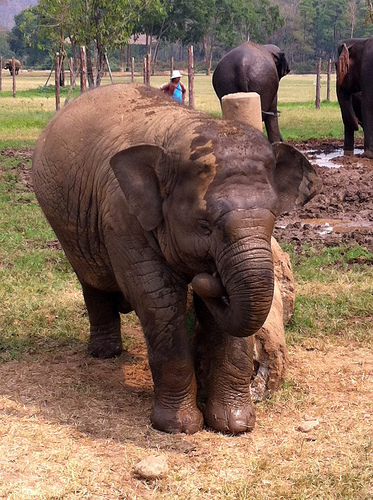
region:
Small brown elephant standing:
[9, 68, 307, 428]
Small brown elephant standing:
[198, 35, 370, 220]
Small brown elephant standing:
[318, 31, 371, 162]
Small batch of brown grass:
[21, 415, 61, 469]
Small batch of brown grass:
[347, 458, 366, 491]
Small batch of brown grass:
[300, 455, 317, 498]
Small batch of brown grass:
[239, 465, 269, 499]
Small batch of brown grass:
[199, 467, 230, 498]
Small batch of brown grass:
[109, 453, 127, 496]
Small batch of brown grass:
[74, 377, 142, 440]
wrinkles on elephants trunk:
[234, 247, 262, 314]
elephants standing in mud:
[223, 25, 372, 139]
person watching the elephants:
[156, 67, 193, 107]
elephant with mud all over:
[143, 123, 284, 435]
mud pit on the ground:
[282, 129, 362, 251]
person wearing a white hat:
[159, 64, 196, 105]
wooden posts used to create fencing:
[49, 47, 70, 109]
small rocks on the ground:
[120, 415, 333, 488]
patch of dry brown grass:
[18, 333, 360, 493]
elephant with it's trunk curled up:
[142, 133, 282, 414]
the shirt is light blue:
[176, 91, 180, 97]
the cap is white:
[170, 71, 184, 76]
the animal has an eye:
[199, 223, 212, 230]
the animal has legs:
[127, 334, 253, 432]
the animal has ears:
[107, 144, 156, 229]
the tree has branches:
[111, 1, 147, 35]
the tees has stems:
[137, 37, 155, 50]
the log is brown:
[187, 48, 193, 102]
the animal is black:
[213, 47, 295, 88]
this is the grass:
[9, 109, 35, 121]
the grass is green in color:
[11, 111, 35, 126]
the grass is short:
[6, 111, 29, 118]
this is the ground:
[46, 364, 109, 430]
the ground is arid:
[22, 403, 82, 445]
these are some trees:
[30, 2, 209, 68]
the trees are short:
[63, 7, 188, 58]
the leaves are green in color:
[70, 7, 174, 32]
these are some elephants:
[50, 22, 371, 321]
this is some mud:
[329, 165, 352, 192]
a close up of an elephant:
[21, 70, 311, 322]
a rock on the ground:
[131, 454, 173, 479]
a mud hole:
[321, 147, 369, 232]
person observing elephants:
[156, 66, 189, 98]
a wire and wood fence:
[8, 55, 71, 99]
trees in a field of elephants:
[162, 2, 221, 73]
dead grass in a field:
[235, 441, 293, 474]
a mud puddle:
[316, 149, 328, 163]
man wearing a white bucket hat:
[167, 68, 179, 77]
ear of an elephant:
[103, 148, 169, 236]